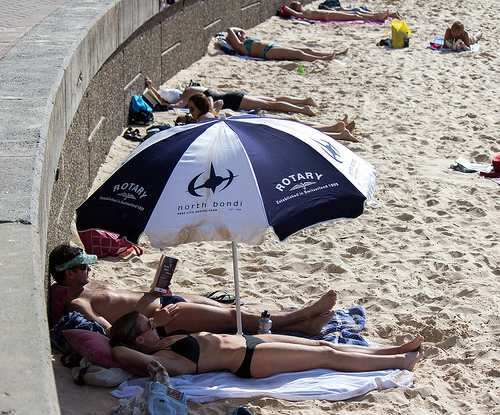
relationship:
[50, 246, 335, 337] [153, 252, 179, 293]
man reading book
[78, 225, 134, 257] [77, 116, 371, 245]
chair under umbrella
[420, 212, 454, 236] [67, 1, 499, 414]
foot print in sand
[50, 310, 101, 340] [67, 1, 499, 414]
jeans on beach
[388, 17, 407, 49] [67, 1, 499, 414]
bag in sand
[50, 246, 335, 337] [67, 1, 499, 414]
man laying in sand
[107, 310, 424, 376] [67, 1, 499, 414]
woman laying on sand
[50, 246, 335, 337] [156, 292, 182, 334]
man wearing speedo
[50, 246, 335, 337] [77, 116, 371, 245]
man underneath umbrella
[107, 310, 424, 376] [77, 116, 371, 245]
woman underneath umbrella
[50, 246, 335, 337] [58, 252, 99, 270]
man wearing visor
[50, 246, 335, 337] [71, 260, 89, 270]
man wearing sunglasses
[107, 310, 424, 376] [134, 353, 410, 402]
woman laying on top of towel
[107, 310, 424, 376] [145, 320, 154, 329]
woman wearing sunglasses